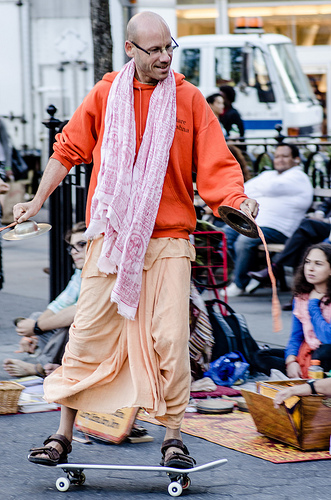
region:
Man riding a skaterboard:
[10, 10, 257, 488]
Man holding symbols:
[2, 3, 275, 256]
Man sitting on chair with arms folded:
[213, 123, 320, 315]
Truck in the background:
[1, 1, 326, 135]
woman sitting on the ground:
[264, 230, 329, 389]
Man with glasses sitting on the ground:
[1, 208, 108, 405]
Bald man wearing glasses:
[100, 6, 201, 97]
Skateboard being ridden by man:
[22, 433, 255, 494]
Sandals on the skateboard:
[19, 421, 271, 486]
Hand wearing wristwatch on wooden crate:
[240, 367, 329, 459]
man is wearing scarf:
[67, 8, 239, 292]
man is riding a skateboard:
[35, 370, 216, 495]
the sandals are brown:
[14, 422, 230, 494]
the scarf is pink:
[86, 50, 198, 328]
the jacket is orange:
[34, 65, 326, 299]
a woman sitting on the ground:
[229, 205, 330, 427]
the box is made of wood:
[228, 358, 327, 442]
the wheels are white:
[58, 467, 203, 499]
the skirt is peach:
[57, 214, 211, 463]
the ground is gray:
[4, 424, 45, 479]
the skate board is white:
[19, 409, 211, 498]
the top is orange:
[79, 89, 259, 237]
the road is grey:
[248, 479, 311, 498]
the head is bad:
[105, 10, 200, 102]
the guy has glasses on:
[113, 19, 261, 271]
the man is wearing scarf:
[61, 62, 267, 264]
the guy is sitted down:
[249, 153, 310, 236]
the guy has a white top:
[244, 167, 317, 232]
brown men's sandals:
[20, 425, 79, 468]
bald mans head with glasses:
[119, 9, 178, 86]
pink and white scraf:
[81, 47, 171, 322]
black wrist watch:
[302, 373, 323, 399]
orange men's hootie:
[46, 48, 275, 249]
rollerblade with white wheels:
[27, 446, 237, 490]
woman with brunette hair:
[282, 234, 322, 374]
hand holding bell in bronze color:
[0, 192, 57, 244]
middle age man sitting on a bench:
[205, 131, 325, 269]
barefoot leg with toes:
[0, 345, 71, 383]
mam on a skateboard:
[13, 6, 236, 496]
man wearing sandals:
[23, 423, 195, 468]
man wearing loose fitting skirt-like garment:
[38, 224, 196, 437]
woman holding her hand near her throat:
[282, 240, 328, 360]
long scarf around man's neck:
[90, 5, 171, 304]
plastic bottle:
[300, 351, 325, 383]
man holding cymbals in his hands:
[1, 181, 264, 249]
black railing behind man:
[33, 98, 326, 306]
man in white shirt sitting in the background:
[214, 135, 311, 256]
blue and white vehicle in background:
[161, 10, 326, 163]